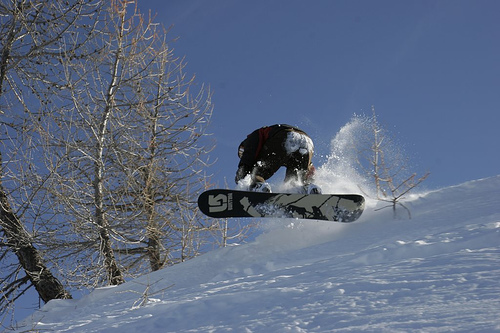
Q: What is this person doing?
A: Snowboarding.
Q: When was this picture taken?
A: In the winter.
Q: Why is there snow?
A: Because it's cold.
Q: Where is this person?
A: In the snow.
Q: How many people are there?
A: One.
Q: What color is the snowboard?
A: Black and white.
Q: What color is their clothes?
A: Black.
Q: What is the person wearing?
A: Snow gear.